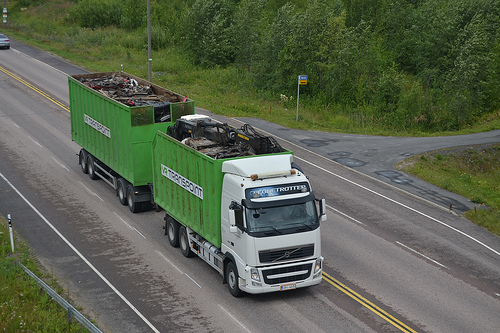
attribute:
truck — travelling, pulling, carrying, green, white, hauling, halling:
[141, 136, 334, 304]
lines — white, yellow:
[339, 253, 371, 312]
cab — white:
[229, 183, 312, 224]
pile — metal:
[187, 110, 255, 159]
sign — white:
[295, 70, 315, 88]